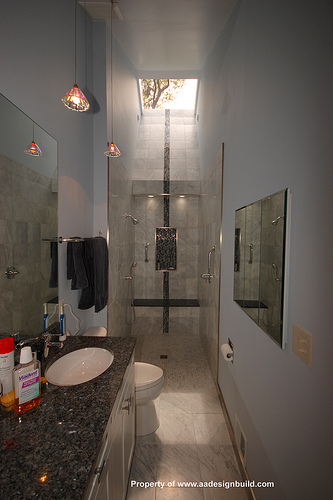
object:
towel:
[66, 235, 109, 313]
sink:
[47, 334, 111, 393]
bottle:
[13, 343, 42, 417]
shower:
[118, 207, 217, 280]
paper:
[220, 343, 234, 363]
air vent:
[292, 325, 312, 369]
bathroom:
[1, 0, 333, 499]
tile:
[157, 412, 195, 444]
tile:
[192, 412, 232, 445]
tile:
[154, 442, 201, 486]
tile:
[129, 442, 157, 481]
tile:
[196, 443, 247, 486]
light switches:
[290, 323, 311, 362]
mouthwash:
[12, 345, 42, 415]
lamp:
[59, 0, 89, 113]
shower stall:
[116, 65, 220, 363]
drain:
[159, 352, 167, 361]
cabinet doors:
[122, 381, 134, 489]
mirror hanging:
[0, 91, 60, 336]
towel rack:
[58, 234, 105, 243]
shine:
[126, 67, 222, 183]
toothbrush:
[59, 301, 64, 336]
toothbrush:
[41, 303, 48, 328]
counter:
[0, 334, 137, 499]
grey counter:
[75, 334, 134, 354]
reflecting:
[151, 391, 208, 448]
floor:
[126, 332, 258, 499]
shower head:
[124, 211, 139, 225]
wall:
[106, 17, 135, 343]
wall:
[192, 0, 332, 499]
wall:
[126, 111, 218, 304]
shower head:
[270, 212, 288, 225]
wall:
[3, 0, 97, 365]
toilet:
[79, 323, 164, 439]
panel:
[134, 68, 200, 119]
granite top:
[2, 335, 137, 499]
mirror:
[233, 188, 288, 352]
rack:
[59, 234, 106, 243]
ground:
[174, 343, 198, 383]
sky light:
[131, 69, 205, 125]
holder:
[226, 337, 236, 363]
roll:
[221, 343, 234, 362]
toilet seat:
[134, 359, 164, 391]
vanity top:
[0, 332, 135, 499]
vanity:
[2, 188, 136, 500]